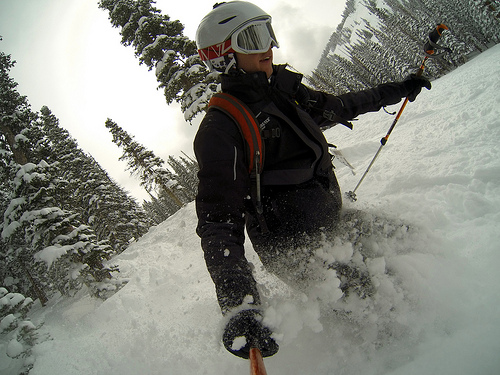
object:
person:
[188, 2, 430, 363]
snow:
[31, 44, 500, 374]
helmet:
[190, 0, 284, 67]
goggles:
[228, 22, 281, 57]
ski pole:
[348, 20, 445, 205]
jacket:
[185, 68, 399, 318]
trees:
[0, 31, 158, 302]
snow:
[258, 200, 496, 374]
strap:
[205, 92, 269, 170]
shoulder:
[188, 85, 264, 170]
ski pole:
[249, 345, 270, 374]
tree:
[99, 114, 188, 213]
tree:
[96, 0, 224, 127]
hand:
[403, 70, 432, 104]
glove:
[221, 313, 279, 362]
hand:
[219, 314, 281, 361]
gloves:
[393, 70, 435, 103]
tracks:
[0, 198, 193, 373]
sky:
[0, 0, 347, 211]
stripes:
[230, 149, 241, 188]